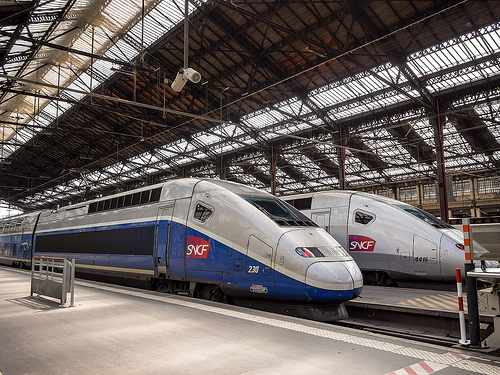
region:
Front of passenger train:
[175, 165, 370, 330]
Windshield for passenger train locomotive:
[235, 180, 320, 240]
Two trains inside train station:
[15, 125, 495, 350]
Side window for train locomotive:
[180, 195, 220, 230]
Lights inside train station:
[160, 45, 205, 222]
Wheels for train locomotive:
[170, 276, 346, 323]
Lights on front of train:
[280, 238, 367, 273]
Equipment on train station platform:
[15, 246, 91, 328]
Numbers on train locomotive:
[404, 247, 439, 279]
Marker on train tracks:
[445, 258, 476, 353]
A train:
[320, 126, 460, 267]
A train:
[148, 151, 343, 371]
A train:
[228, 193, 341, 365]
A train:
[218, 190, 293, 317]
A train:
[179, 151, 284, 347]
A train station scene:
[17, 42, 497, 363]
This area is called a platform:
[6, 266, 411, 371]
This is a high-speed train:
[29, 180, 369, 299]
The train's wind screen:
[239, 191, 316, 231]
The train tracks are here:
[351, 309, 465, 354]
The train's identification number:
[243, 262, 264, 277]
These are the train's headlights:
[292, 242, 350, 262]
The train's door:
[151, 201, 176, 282]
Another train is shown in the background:
[320, 182, 496, 282]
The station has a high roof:
[24, 25, 481, 170]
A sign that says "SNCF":
[185, 236, 215, 261]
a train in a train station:
[14, 176, 374, 316]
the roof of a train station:
[15, 11, 170, 146]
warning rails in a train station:
[428, 209, 495, 299]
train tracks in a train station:
[199, 272, 476, 364]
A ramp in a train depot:
[78, 291, 335, 372]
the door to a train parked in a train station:
[140, 200, 191, 278]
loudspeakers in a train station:
[157, 56, 215, 102]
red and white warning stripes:
[377, 342, 431, 374]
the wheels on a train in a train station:
[145, 266, 239, 308]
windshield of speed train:
[235, 186, 317, 244]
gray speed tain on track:
[308, 181, 485, 291]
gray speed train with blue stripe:
[46, 206, 382, 312]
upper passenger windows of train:
[86, 183, 187, 214]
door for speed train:
[149, 200, 185, 281]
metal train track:
[328, 251, 498, 374]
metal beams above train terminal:
[66, 91, 317, 180]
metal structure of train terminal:
[298, 94, 488, 208]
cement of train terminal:
[32, 303, 270, 373]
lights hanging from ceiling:
[154, 11, 236, 116]